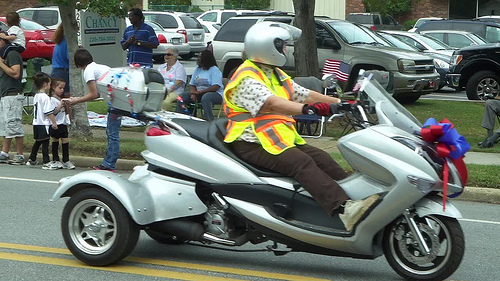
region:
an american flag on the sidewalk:
[312, 50, 356, 88]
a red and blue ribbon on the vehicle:
[412, 104, 479, 203]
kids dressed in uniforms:
[23, 72, 78, 173]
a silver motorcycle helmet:
[238, 10, 302, 76]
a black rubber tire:
[54, 177, 135, 272]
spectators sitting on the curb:
[126, 8, 220, 113]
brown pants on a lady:
[232, 112, 364, 227]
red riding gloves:
[298, 93, 338, 122]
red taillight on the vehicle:
[140, 121, 174, 145]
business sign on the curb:
[77, 9, 129, 63]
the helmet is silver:
[239, 18, 291, 65]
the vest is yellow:
[221, 54, 303, 156]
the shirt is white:
[34, 94, 74, 125]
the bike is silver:
[134, 116, 444, 253]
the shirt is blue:
[115, 29, 162, 60]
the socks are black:
[54, 140, 75, 157]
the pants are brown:
[267, 145, 354, 197]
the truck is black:
[447, 45, 497, 75]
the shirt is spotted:
[235, 82, 265, 114]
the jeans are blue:
[93, 128, 128, 163]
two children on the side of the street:
[21, 75, 79, 172]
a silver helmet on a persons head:
[243, 21, 300, 65]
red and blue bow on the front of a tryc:
[423, 111, 477, 193]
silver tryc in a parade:
[26, 26, 476, 269]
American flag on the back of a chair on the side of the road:
[318, 58, 353, 86]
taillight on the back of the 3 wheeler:
[141, 121, 171, 138]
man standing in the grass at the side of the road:
[118, 8, 159, 73]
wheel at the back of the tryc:
[50, 188, 137, 267]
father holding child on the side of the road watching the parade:
[1, 7, 28, 169]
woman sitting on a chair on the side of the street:
[154, 46, 184, 115]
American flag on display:
[321, 52, 356, 97]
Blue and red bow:
[417, 107, 473, 208]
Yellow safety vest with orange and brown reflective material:
[225, 57, 312, 153]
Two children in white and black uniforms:
[30, 68, 76, 168]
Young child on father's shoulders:
[1, 7, 26, 62]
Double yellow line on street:
[0, 235, 329, 279]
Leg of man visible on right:
[476, 91, 498, 148]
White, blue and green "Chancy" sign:
[76, 7, 126, 68]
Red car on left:
[0, 14, 55, 57]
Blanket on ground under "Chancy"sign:
[86, 103, 150, 136]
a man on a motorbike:
[33, 31, 464, 279]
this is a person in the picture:
[213, 19, 379, 239]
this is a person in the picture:
[72, 45, 136, 174]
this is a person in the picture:
[110, 4, 160, 75]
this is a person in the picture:
[160, 44, 187, 104]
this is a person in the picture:
[173, 47, 231, 130]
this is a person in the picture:
[51, 20, 85, 84]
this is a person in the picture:
[1, 10, 26, 172]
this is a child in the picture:
[27, 69, 57, 171]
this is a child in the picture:
[52, 74, 77, 170]